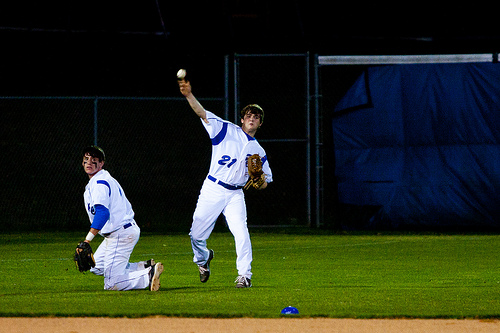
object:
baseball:
[175, 65, 186, 79]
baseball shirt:
[77, 168, 138, 238]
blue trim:
[96, 178, 111, 196]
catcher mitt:
[248, 157, 267, 192]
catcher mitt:
[73, 242, 97, 274]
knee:
[102, 271, 119, 290]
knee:
[86, 260, 101, 274]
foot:
[195, 247, 215, 284]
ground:
[2, 230, 498, 318]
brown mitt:
[239, 151, 265, 188]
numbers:
[218, 155, 240, 167]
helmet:
[278, 302, 300, 318]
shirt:
[202, 109, 272, 189]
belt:
[204, 172, 250, 188]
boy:
[174, 79, 272, 290]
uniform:
[187, 110, 272, 278]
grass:
[3, 234, 493, 314]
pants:
[188, 184, 254, 280]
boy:
[73, 144, 165, 293]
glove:
[73, 240, 95, 277]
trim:
[208, 117, 229, 149]